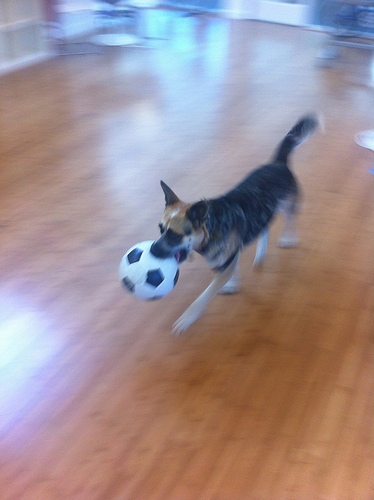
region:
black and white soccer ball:
[119, 237, 178, 302]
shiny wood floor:
[83, 87, 209, 170]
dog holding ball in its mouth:
[119, 114, 328, 334]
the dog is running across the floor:
[117, 111, 320, 334]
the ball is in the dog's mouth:
[117, 240, 180, 299]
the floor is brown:
[209, 367, 342, 495]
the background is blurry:
[43, 9, 240, 121]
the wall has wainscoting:
[4, 17, 51, 66]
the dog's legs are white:
[172, 266, 236, 335]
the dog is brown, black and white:
[148, 116, 322, 335]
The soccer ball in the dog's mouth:
[119, 243, 177, 301]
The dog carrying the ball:
[149, 108, 327, 338]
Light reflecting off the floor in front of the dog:
[0, 296, 66, 422]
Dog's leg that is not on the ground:
[168, 268, 236, 335]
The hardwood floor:
[0, 12, 371, 497]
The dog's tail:
[272, 103, 323, 163]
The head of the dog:
[148, 190, 203, 266]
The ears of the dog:
[154, 179, 212, 224]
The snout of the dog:
[149, 233, 190, 262]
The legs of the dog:
[160, 201, 302, 338]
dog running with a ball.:
[91, 81, 339, 350]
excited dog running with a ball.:
[45, 50, 349, 376]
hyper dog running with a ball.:
[116, 113, 343, 373]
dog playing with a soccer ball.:
[89, 47, 329, 381]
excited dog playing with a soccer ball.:
[88, 59, 328, 357]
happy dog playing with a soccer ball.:
[95, 97, 354, 371]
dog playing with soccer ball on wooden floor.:
[113, 74, 337, 344]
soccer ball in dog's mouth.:
[106, 193, 200, 299]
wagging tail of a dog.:
[261, 109, 340, 170]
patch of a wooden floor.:
[22, 379, 314, 482]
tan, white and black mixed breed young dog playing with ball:
[149, 107, 320, 332]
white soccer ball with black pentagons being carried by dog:
[116, 242, 175, 297]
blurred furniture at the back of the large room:
[44, 0, 194, 83]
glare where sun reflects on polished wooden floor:
[1, 292, 64, 425]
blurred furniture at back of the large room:
[313, 0, 370, 80]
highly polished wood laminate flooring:
[0, 8, 371, 496]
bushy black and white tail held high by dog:
[269, 107, 324, 158]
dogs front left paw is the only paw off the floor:
[167, 309, 193, 334]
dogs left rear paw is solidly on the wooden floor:
[274, 234, 295, 247]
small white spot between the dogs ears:
[171, 206, 180, 219]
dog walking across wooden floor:
[96, 76, 325, 338]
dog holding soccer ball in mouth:
[94, 158, 225, 339]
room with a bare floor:
[53, 0, 234, 176]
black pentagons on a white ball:
[116, 231, 179, 302]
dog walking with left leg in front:
[114, 184, 255, 367]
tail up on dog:
[225, 97, 333, 284]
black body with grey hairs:
[198, 158, 305, 259]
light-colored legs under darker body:
[156, 194, 318, 336]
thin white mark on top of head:
[154, 195, 191, 245]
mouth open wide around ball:
[133, 237, 199, 270]